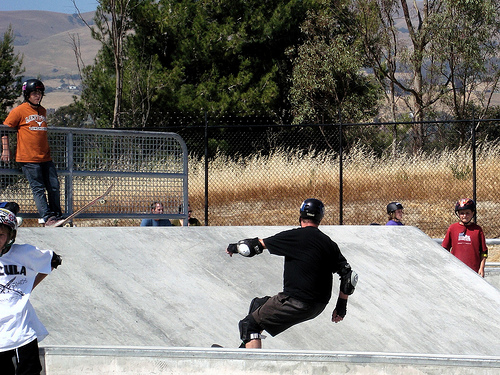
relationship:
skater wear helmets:
[208, 190, 364, 350] [293, 195, 332, 234]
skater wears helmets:
[2, 71, 85, 236] [15, 72, 50, 109]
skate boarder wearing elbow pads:
[208, 190, 364, 350] [232, 234, 366, 293]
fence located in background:
[183, 118, 497, 206] [55, 54, 499, 115]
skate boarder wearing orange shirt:
[2, 71, 85, 236] [2, 100, 62, 166]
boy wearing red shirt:
[441, 193, 497, 283] [436, 221, 488, 278]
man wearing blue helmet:
[0, 199, 69, 375] [2, 198, 27, 252]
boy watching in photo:
[441, 193, 497, 283] [4, 4, 500, 375]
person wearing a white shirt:
[0, 199, 69, 375] [1, 239, 59, 355]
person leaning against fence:
[2, 71, 85, 236] [1, 121, 199, 226]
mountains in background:
[4, 5, 114, 86] [8, 5, 499, 55]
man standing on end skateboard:
[2, 71, 85, 236] [48, 178, 123, 235]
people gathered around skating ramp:
[132, 195, 208, 231] [25, 218, 499, 368]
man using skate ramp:
[208, 190, 364, 350] [25, 218, 499, 368]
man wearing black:
[208, 190, 364, 350] [222, 227, 361, 346]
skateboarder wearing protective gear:
[208, 190, 364, 350] [232, 234, 366, 293]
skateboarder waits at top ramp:
[2, 71, 85, 236] [25, 218, 499, 368]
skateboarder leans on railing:
[2, 71, 85, 236] [1, 121, 199, 226]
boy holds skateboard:
[2, 71, 85, 236] [48, 178, 123, 235]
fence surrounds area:
[183, 118, 497, 206] [5, 59, 495, 203]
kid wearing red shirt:
[441, 193, 497, 283] [436, 221, 488, 278]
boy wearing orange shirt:
[2, 71, 85, 236] [2, 100, 62, 166]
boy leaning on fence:
[2, 71, 85, 236] [1, 121, 199, 226]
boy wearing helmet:
[441, 193, 497, 283] [446, 194, 487, 232]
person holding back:
[0, 199, 69, 375] [3, 198, 68, 314]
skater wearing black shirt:
[208, 190, 364, 350] [261, 224, 355, 309]